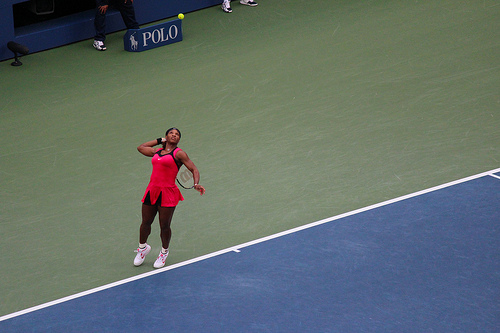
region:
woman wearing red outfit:
[132, 122, 212, 257]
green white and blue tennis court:
[380, 179, 415, 220]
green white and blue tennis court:
[53, 279, 108, 306]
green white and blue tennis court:
[386, 161, 418, 198]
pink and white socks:
[132, 246, 169, 258]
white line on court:
[194, 196, 304, 263]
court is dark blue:
[325, 279, 432, 316]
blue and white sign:
[130, 2, 186, 65]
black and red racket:
[172, 162, 199, 194]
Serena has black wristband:
[143, 130, 168, 157]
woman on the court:
[82, 107, 224, 256]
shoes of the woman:
[119, 237, 179, 280]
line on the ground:
[248, 170, 358, 261]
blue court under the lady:
[215, 250, 342, 329]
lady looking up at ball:
[93, 108, 214, 238]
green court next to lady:
[235, 65, 362, 155]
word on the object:
[120, 13, 192, 60]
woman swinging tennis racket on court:
[126, 119, 209, 274]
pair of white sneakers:
[130, 243, 170, 272]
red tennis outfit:
[137, 142, 189, 212]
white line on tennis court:
[1, 166, 497, 331]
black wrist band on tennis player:
[152, 133, 165, 146]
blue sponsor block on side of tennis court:
[118, 13, 186, 55]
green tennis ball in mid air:
[174, 10, 187, 22]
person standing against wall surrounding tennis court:
[83, 0, 147, 53]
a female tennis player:
[128, 126, 203, 268]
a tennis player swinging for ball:
[133, 12, 205, 268]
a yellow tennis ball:
[177, 12, 185, 19]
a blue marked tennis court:
[1, 166, 498, 331]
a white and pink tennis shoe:
[133, 244, 150, 266]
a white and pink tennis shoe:
[153, 247, 166, 267]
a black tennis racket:
[176, 163, 196, 189]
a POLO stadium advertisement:
[120, 19, 182, 51]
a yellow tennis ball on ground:
[178, 12, 185, 19]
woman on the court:
[109, 112, 219, 233]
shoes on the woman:
[104, 236, 185, 287]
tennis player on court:
[94, 108, 220, 272]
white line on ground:
[256, 172, 371, 268]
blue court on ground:
[283, 235, 414, 306]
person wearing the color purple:
[103, 94, 252, 251]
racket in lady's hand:
[165, 140, 210, 204]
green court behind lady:
[234, 99, 354, 181]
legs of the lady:
[121, 208, 185, 255]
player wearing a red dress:
[141, 139, 190, 213]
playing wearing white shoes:
[125, 234, 173, 272]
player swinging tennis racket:
[149, 131, 216, 199]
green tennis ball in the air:
[172, 12, 187, 23]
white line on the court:
[195, 232, 270, 267]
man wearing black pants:
[88, 3, 140, 36]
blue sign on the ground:
[123, 17, 185, 48]